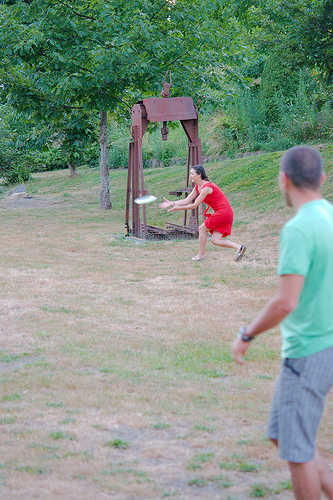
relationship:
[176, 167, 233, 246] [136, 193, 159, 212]
woman catching frisbee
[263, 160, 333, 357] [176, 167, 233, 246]
man watching woman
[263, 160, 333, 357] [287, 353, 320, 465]
man wearing shorts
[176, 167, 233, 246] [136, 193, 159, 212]
woman playing frisbee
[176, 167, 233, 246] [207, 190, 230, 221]
woman with dress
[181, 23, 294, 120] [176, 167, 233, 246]
trees near woman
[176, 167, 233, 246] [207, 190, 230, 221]
woman in dress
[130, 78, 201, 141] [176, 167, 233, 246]
well near woman